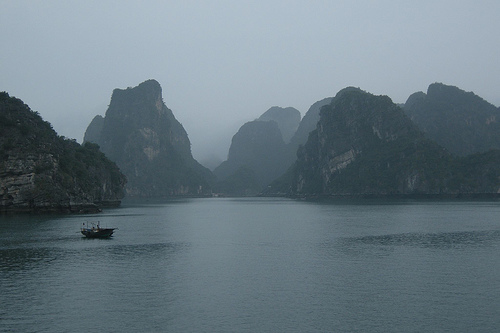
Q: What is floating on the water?
A: A boat.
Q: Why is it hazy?
A: There is fog.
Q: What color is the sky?
A: Grey.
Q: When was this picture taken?
A: During the day.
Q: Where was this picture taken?
A: A cliff-side lake.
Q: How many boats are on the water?
A: One.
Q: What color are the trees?
A: Green.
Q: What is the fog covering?
A: More cliffs.